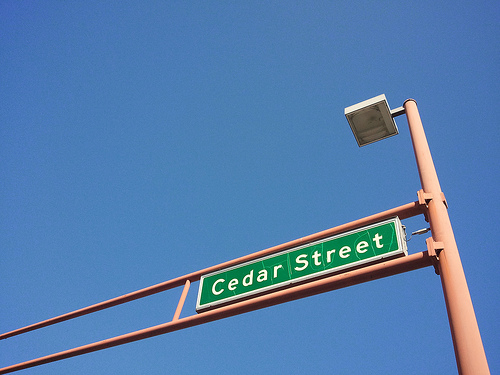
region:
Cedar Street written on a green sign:
[171, 212, 422, 297]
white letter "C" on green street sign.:
[205, 270, 225, 296]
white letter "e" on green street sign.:
[225, 270, 240, 290]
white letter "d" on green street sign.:
[240, 265, 255, 286]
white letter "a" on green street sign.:
[251, 261, 267, 286]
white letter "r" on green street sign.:
[267, 255, 282, 285]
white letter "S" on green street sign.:
[290, 245, 307, 270]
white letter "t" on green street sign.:
[310, 240, 321, 266]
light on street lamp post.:
[325, 80, 441, 185]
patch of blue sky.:
[0, 26, 290, 208]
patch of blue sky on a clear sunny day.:
[20, 31, 285, 216]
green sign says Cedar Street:
[173, 208, 425, 325]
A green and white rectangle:
[159, 239, 428, 315]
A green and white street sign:
[175, 192, 458, 324]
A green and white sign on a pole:
[180, 187, 463, 324]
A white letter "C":
[201, 264, 226, 302]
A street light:
[327, 83, 440, 181]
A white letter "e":
[223, 268, 240, 296]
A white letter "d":
[239, 265, 256, 295]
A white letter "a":
[257, 266, 272, 291]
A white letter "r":
[271, 258, 284, 285]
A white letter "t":
[307, 246, 325, 274]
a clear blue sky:
[37, 77, 283, 164]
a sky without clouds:
[58, 118, 231, 247]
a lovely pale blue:
[14, 71, 286, 241]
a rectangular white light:
[331, 83, 401, 165]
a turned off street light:
[321, 85, 407, 160]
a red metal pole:
[395, 75, 498, 363]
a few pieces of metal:
[30, 274, 195, 354]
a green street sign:
[178, 211, 430, 326]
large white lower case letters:
[188, 235, 421, 296]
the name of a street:
[196, 220, 420, 313]